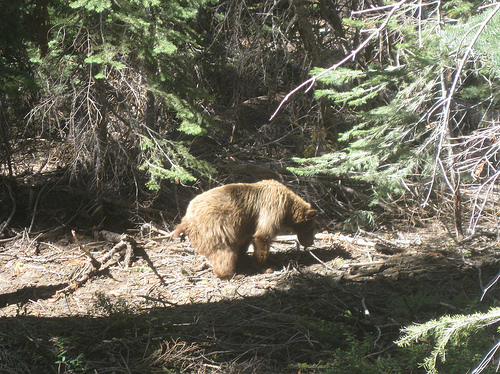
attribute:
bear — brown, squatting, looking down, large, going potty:
[178, 180, 324, 286]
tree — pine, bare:
[44, 0, 218, 199]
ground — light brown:
[8, 116, 491, 372]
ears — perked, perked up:
[301, 201, 321, 225]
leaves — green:
[156, 17, 185, 58]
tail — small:
[173, 214, 185, 236]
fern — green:
[45, 333, 92, 373]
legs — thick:
[203, 229, 245, 290]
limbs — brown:
[60, 94, 139, 177]